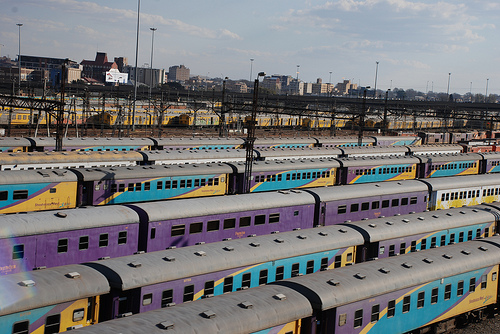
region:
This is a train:
[120, 173, 327, 240]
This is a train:
[300, 169, 436, 216]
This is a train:
[422, 169, 499, 206]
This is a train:
[1, 193, 144, 270]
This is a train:
[0, 246, 114, 327]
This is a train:
[92, 216, 376, 299]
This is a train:
[338, 199, 498, 252]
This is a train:
[123, 265, 345, 331]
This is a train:
[287, 240, 492, 329]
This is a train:
[222, 124, 349, 193]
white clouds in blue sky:
[25, 11, 66, 38]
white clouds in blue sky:
[51, 8, 84, 43]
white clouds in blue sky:
[71, 9, 125, 46]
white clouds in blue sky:
[173, 10, 203, 60]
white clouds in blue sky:
[210, 6, 237, 53]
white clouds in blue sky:
[272, 10, 297, 55]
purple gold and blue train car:
[81, 162, 231, 194]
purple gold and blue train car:
[237, 158, 330, 185]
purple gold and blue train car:
[302, 270, 490, 308]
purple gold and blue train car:
[404, 147, 495, 172]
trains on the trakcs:
[55, 33, 471, 330]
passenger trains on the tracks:
[47, 91, 412, 329]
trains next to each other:
[12, 80, 419, 330]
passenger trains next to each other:
[62, 93, 423, 329]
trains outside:
[52, 77, 443, 332]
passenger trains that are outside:
[78, 79, 446, 326]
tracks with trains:
[67, 46, 425, 331]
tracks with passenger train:
[53, 103, 445, 329]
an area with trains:
[19, 90, 478, 332]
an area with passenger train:
[25, 94, 497, 296]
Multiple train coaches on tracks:
[0, 0, 497, 331]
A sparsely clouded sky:
[3, 0, 498, 95]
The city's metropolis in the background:
[2, 47, 498, 103]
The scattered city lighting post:
[17, 0, 489, 135]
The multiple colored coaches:
[2, 96, 497, 331]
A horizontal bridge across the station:
[64, 76, 498, 113]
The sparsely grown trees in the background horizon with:
[200, 77, 496, 100]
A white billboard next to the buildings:
[105, 70, 126, 82]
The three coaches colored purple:
[0, 181, 431, 274]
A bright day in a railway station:
[0, 0, 499, 333]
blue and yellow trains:
[15, 121, 432, 215]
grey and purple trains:
[6, 179, 386, 260]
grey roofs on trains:
[24, 134, 447, 326]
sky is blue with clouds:
[183, 0, 370, 87]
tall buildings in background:
[36, 51, 386, 120]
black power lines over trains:
[76, 34, 464, 179]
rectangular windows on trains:
[60, 141, 485, 267]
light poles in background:
[7, 19, 494, 133]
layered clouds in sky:
[2, 16, 259, 42]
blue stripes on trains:
[92, 117, 495, 276]